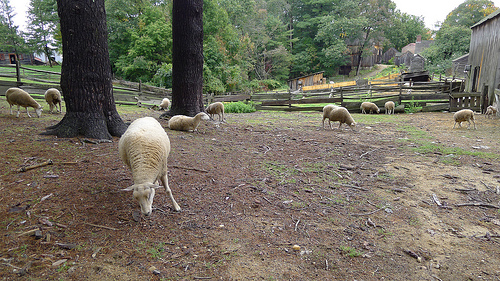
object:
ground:
[0, 97, 500, 280]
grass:
[222, 100, 255, 112]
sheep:
[118, 116, 181, 217]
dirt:
[0, 61, 499, 281]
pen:
[391, 149, 500, 219]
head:
[121, 183, 165, 217]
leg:
[160, 174, 182, 211]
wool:
[118, 117, 171, 184]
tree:
[35, 0, 126, 140]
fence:
[0, 60, 490, 113]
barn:
[463, 10, 500, 115]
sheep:
[168, 112, 210, 135]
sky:
[395, 0, 499, 38]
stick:
[20, 158, 77, 173]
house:
[1, 51, 48, 66]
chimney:
[416, 35, 421, 44]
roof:
[0, 38, 31, 47]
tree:
[347, 0, 396, 73]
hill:
[1, 65, 60, 97]